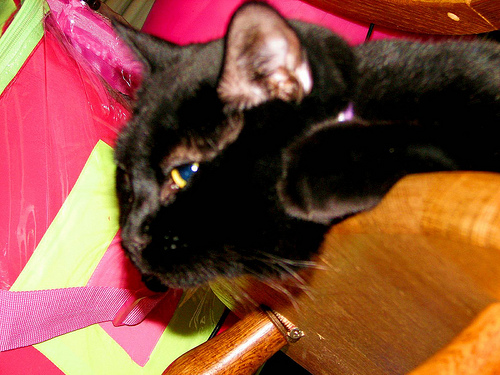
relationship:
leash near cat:
[1, 286, 181, 353] [109, 14, 484, 292]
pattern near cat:
[2, 5, 230, 372] [109, 1, 500, 321]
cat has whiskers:
[109, 14, 484, 292] [238, 252, 358, 328]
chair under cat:
[156, 170, 480, 370] [109, 14, 484, 292]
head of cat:
[112, 18, 353, 279] [109, 14, 484, 292]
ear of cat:
[213, 0, 320, 107] [109, 14, 484, 292]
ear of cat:
[112, 10, 176, 78] [109, 14, 484, 292]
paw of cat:
[276, 123, 413, 227] [109, 14, 484, 292]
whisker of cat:
[244, 249, 358, 322] [109, 14, 484, 292]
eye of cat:
[162, 158, 211, 192] [109, 14, 484, 292]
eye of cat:
[162, 158, 211, 192] [109, 1, 500, 321]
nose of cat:
[120, 225, 145, 262] [109, 14, 484, 292]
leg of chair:
[172, 312, 306, 371] [156, 170, 480, 370]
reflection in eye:
[165, 154, 205, 188] [154, 147, 213, 193]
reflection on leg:
[244, 323, 276, 358] [155, 312, 290, 375]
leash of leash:
[1, 286, 181, 353] [1, 243, 174, 343]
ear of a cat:
[213, 0, 320, 107] [109, 14, 484, 292]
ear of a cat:
[92, 0, 176, 78] [109, 14, 484, 292]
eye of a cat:
[162, 152, 215, 192] [109, 14, 484, 292]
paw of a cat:
[260, 108, 420, 232] [99, 14, 480, 362]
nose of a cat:
[120, 225, 145, 262] [109, 14, 484, 292]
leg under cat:
[155, 312, 290, 375] [90, 3, 462, 306]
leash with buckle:
[1, 286, 181, 353] [112, 280, 177, 329]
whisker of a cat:
[244, 249, 358, 322] [109, 14, 484, 292]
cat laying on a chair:
[109, 1, 500, 321] [156, 170, 480, 370]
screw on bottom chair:
[262, 300, 308, 345] [248, 226, 434, 364]